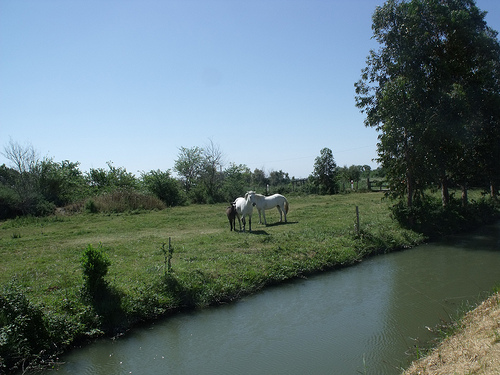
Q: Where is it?
A: This is at the field.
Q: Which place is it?
A: It is a field.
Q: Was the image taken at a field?
A: Yes, it was taken in a field.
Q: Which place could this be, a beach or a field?
A: It is a field.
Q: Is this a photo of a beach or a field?
A: It is showing a field.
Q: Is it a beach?
A: No, it is a field.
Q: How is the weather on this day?
A: It is clear.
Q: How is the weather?
A: It is clear.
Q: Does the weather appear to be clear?
A: Yes, it is clear.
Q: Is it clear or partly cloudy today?
A: It is clear.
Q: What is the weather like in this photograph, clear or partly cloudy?
A: It is clear.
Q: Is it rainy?
A: No, it is clear.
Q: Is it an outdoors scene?
A: Yes, it is outdoors.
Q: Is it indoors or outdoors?
A: It is outdoors.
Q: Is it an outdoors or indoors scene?
A: It is outdoors.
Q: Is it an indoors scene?
A: No, it is outdoors.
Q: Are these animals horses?
A: Yes, all the animals are horses.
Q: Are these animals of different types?
A: No, all the animals are horses.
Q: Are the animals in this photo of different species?
A: No, all the animals are horses.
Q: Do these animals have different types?
A: No, all the animals are horses.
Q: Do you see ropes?
A: No, there are no ropes.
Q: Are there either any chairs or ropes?
A: No, there are no ropes or chairs.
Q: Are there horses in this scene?
A: Yes, there is a horse.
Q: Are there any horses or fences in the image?
A: Yes, there is a horse.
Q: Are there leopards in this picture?
A: No, there are no leopards.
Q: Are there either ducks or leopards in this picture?
A: No, there are no leopards or ducks.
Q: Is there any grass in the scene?
A: Yes, there is grass.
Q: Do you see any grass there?
A: Yes, there is grass.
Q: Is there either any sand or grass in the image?
A: Yes, there is grass.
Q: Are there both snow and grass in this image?
A: No, there is grass but no snow.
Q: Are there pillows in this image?
A: No, there are no pillows.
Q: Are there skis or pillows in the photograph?
A: No, there are no pillows or skis.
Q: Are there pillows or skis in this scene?
A: No, there are no pillows or skis.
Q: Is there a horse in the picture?
A: Yes, there is a horse.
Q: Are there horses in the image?
A: Yes, there is a horse.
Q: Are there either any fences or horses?
A: Yes, there is a horse.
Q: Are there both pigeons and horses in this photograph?
A: No, there is a horse but no pigeons.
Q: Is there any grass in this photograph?
A: Yes, there is grass.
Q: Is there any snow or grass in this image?
A: Yes, there is grass.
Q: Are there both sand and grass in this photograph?
A: No, there is grass but no sand.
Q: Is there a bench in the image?
A: No, there are no benches.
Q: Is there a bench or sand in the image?
A: No, there are no benches or sand.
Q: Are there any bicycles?
A: No, there are no bicycles.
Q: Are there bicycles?
A: No, there are no bicycles.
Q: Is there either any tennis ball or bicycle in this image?
A: No, there are no bicycles or tennis balls.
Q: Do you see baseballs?
A: No, there are no baseballs.